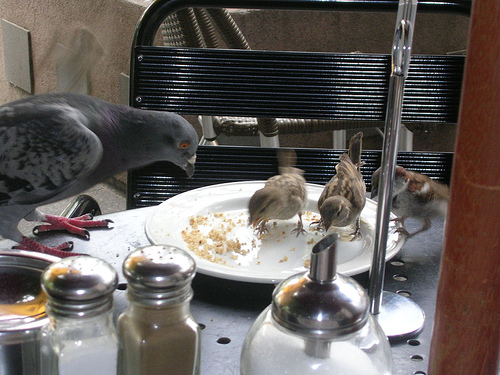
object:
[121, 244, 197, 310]
lids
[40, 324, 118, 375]
salt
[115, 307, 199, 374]
pepper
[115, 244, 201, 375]
pepper shaker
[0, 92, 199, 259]
bird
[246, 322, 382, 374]
sugar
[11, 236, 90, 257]
toes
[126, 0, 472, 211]
chair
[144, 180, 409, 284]
plate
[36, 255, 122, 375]
bottle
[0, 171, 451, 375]
table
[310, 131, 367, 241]
birds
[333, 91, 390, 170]
ground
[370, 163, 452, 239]
bird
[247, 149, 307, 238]
bird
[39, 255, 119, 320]
lids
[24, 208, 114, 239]
foot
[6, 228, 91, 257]
foot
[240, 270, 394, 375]
bottle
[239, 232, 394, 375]
sugar shaker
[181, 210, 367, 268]
crumbs